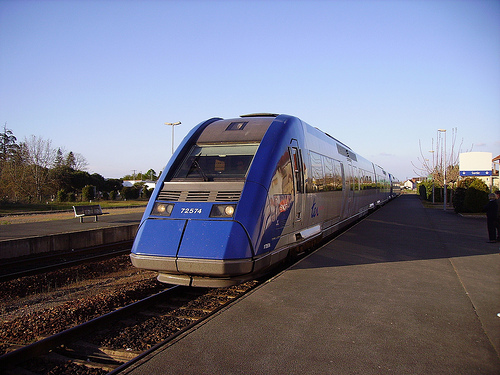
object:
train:
[129, 112, 400, 288]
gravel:
[0, 253, 163, 354]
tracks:
[0, 248, 194, 375]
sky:
[0, 0, 500, 182]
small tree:
[410, 127, 474, 204]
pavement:
[123, 194, 498, 375]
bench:
[72, 204, 109, 223]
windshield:
[163, 142, 259, 183]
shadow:
[275, 194, 500, 270]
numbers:
[181, 208, 203, 214]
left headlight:
[209, 204, 236, 218]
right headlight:
[150, 202, 175, 216]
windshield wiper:
[190, 156, 208, 182]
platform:
[0, 212, 145, 241]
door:
[288, 147, 305, 222]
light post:
[438, 129, 447, 211]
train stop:
[459, 151, 493, 176]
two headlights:
[150, 202, 237, 218]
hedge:
[451, 177, 490, 218]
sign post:
[459, 152, 492, 176]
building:
[492, 180, 500, 215]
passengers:
[296, 150, 400, 194]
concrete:
[0, 238, 30, 260]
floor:
[119, 195, 499, 374]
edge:
[128, 253, 253, 288]